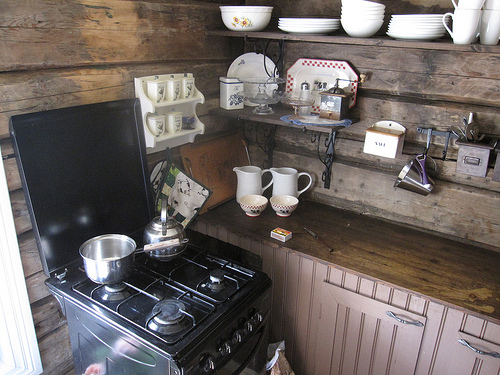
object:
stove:
[42, 242, 272, 375]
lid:
[8, 97, 156, 277]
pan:
[79, 234, 138, 284]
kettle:
[143, 201, 188, 262]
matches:
[270, 227, 292, 243]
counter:
[196, 189, 500, 324]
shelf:
[143, 122, 202, 140]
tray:
[173, 138, 260, 207]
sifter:
[318, 78, 354, 121]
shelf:
[207, 105, 360, 133]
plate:
[284, 58, 358, 109]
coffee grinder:
[318, 78, 354, 120]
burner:
[194, 260, 245, 291]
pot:
[147, 114, 166, 138]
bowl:
[217, 6, 273, 32]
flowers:
[240, 18, 248, 26]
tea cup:
[238, 194, 268, 217]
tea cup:
[269, 195, 299, 217]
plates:
[384, 32, 447, 39]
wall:
[5, 4, 261, 201]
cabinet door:
[315, 281, 427, 374]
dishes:
[278, 26, 341, 36]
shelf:
[203, 27, 500, 53]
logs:
[4, 7, 251, 102]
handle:
[385, 310, 424, 327]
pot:
[164, 111, 183, 134]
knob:
[251, 312, 264, 325]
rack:
[134, 72, 205, 155]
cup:
[394, 153, 437, 196]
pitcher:
[233, 165, 275, 204]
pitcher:
[269, 167, 313, 198]